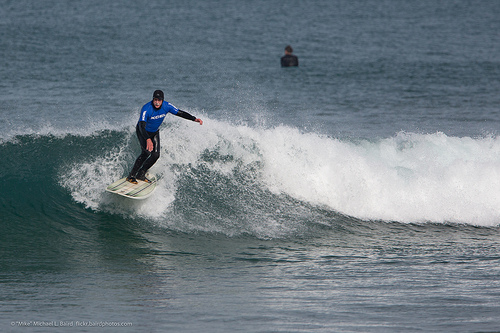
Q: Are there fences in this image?
A: No, there are no fences.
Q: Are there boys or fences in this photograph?
A: No, there are no fences or boys.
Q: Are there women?
A: No, there are no women.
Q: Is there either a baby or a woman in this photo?
A: No, there are no women or babies.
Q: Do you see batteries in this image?
A: No, there are no batteries.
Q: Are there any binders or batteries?
A: No, there are no batteries or binders.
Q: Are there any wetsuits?
A: Yes, there is a wetsuit.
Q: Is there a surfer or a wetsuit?
A: Yes, there is a wetsuit.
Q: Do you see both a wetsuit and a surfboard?
A: Yes, there are both a wetsuit and a surfboard.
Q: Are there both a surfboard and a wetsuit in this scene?
A: Yes, there are both a wetsuit and a surfboard.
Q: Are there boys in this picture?
A: No, there are no boys.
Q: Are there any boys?
A: No, there are no boys.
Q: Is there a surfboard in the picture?
A: Yes, there is a surfboard.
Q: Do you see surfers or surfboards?
A: Yes, there is a surfboard.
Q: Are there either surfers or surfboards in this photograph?
A: Yes, there is a surfboard.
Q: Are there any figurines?
A: No, there are no figurines.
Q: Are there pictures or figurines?
A: No, there are no figurines or pictures.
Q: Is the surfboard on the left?
A: Yes, the surfboard is on the left of the image.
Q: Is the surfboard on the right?
A: No, the surfboard is on the left of the image.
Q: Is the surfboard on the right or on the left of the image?
A: The surfboard is on the left of the image.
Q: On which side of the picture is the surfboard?
A: The surfboard is on the left of the image.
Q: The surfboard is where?
A: The surfboard is in the water.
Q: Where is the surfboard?
A: The surfboard is in the water.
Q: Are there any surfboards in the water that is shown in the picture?
A: Yes, there is a surfboard in the water.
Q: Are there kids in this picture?
A: No, there are no kids.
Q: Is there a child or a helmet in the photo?
A: No, there are no children or helmets.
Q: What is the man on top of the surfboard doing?
A: The man is surfing.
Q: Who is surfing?
A: The man is surfing.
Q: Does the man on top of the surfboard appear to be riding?
A: No, the man is surfing.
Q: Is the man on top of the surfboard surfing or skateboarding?
A: The man is surfing.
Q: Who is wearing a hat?
A: The man is wearing a hat.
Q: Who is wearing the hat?
A: The man is wearing a hat.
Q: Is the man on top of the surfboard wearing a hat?
A: Yes, the man is wearing a hat.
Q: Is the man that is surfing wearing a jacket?
A: No, the man is wearing a hat.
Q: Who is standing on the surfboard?
A: The man is standing on the surfboard.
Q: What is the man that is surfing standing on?
A: The man is standing on the surf board.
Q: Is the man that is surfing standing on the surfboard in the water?
A: Yes, the man is standing on the surfboard.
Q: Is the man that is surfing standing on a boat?
A: No, the man is standing on the surfboard.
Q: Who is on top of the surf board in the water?
A: The man is on top of the surfboard.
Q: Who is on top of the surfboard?
A: The man is on top of the surfboard.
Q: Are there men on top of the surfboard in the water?
A: Yes, there is a man on top of the surfboard.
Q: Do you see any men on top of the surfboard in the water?
A: Yes, there is a man on top of the surfboard.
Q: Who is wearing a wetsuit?
A: The man is wearing a wetsuit.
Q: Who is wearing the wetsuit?
A: The man is wearing a wetsuit.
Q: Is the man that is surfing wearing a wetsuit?
A: Yes, the man is wearing a wetsuit.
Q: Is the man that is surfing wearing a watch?
A: No, the man is wearing a wetsuit.